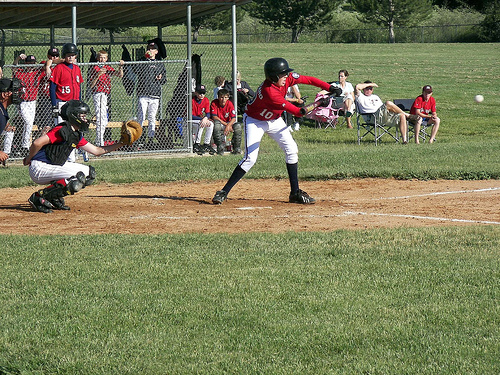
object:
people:
[407, 84, 439, 145]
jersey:
[244, 72, 334, 122]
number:
[257, 107, 266, 116]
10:
[259, 108, 272, 124]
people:
[326, 67, 356, 130]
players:
[46, 42, 85, 162]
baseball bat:
[295, 91, 338, 117]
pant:
[237, 115, 299, 175]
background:
[0, 0, 499, 374]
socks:
[221, 164, 246, 196]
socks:
[285, 161, 298, 191]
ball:
[474, 94, 485, 104]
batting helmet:
[261, 56, 295, 88]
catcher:
[21, 98, 143, 214]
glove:
[118, 117, 143, 145]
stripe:
[236, 118, 249, 171]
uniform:
[221, 72, 329, 192]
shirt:
[352, 91, 385, 116]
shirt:
[210, 99, 238, 119]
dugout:
[0, 0, 238, 169]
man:
[354, 79, 422, 148]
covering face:
[360, 88, 374, 99]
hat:
[262, 57, 292, 84]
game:
[0, 41, 499, 374]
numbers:
[63, 84, 74, 95]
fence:
[1, 61, 191, 165]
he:
[210, 56, 342, 205]